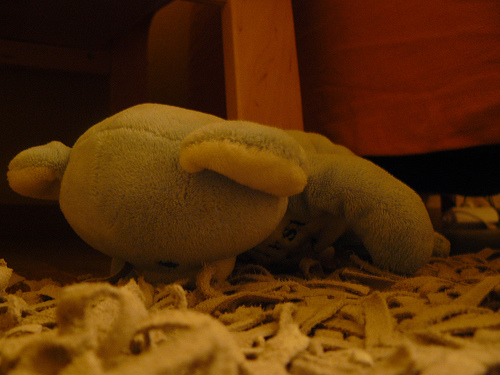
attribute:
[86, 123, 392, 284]
toy — down, laying, stuffing, stuffed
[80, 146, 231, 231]
bear — plush, green, down, tan, stuffed, facedown, lying, here, teddy, facing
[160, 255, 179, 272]
eye — black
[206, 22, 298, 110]
chair leg — wooden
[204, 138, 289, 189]
ear — blush, two tone, tan, white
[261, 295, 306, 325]
floor — white, leather, tan, curly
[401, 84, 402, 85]
chair — brown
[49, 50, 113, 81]
dresser — dark, brown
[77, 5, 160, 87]
panel — wood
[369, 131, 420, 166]
fabric — red